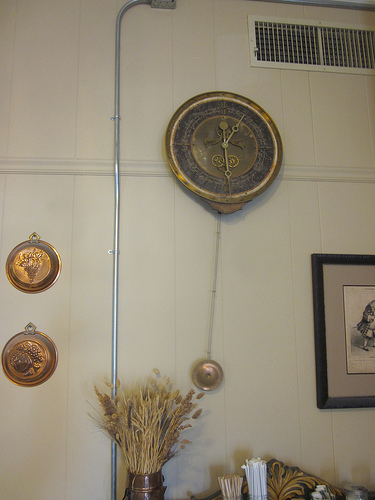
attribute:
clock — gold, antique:
[166, 88, 283, 218]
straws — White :
[241, 457, 270, 498]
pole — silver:
[109, 149, 124, 403]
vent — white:
[246, 13, 372, 70]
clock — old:
[163, 82, 282, 214]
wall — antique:
[283, 77, 371, 169]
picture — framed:
[304, 250, 373, 408]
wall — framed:
[281, 182, 374, 248]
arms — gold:
[217, 111, 247, 185]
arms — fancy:
[219, 113, 246, 185]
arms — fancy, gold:
[218, 111, 243, 180]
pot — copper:
[2, 318, 59, 382]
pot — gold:
[4, 231, 67, 296]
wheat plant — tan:
[88, 370, 205, 467]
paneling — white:
[118, 172, 185, 381]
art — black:
[310, 250, 373, 409]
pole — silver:
[107, 133, 126, 392]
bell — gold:
[194, 360, 223, 391]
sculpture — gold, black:
[268, 464, 340, 498]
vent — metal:
[243, 13, 371, 75]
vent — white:
[240, 7, 362, 86]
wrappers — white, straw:
[240, 453, 270, 494]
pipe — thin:
[110, 187, 121, 381]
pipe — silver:
[110, 190, 122, 383]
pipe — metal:
[111, 188, 120, 386]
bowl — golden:
[1, 308, 71, 400]